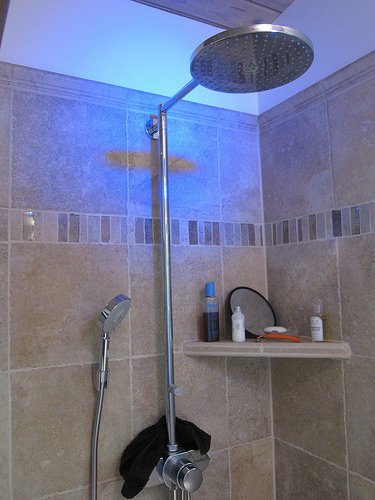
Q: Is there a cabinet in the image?
A: No, there are no cabinets.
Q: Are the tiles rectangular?
A: Yes, the tiles are rectangular.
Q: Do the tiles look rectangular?
A: Yes, the tiles are rectangular.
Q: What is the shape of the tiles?
A: The tiles are rectangular.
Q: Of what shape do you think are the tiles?
A: The tiles are rectangular.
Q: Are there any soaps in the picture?
A: Yes, there is a soap.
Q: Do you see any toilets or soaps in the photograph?
A: Yes, there is a soap.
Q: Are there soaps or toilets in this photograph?
A: Yes, there is a soap.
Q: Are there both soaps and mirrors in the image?
A: Yes, there are both a soap and a mirror.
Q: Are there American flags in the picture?
A: No, there are no American flags.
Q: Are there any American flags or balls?
A: No, there are no American flags or balls.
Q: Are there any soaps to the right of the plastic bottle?
A: Yes, there is a soap to the right of the bottle.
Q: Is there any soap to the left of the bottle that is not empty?
A: No, the soap is to the right of the bottle.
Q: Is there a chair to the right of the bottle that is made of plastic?
A: No, there is a soap to the right of the bottle.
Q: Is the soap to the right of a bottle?
A: Yes, the soap is to the right of a bottle.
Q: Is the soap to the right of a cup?
A: No, the soap is to the right of a bottle.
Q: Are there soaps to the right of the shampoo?
A: Yes, there is a soap to the right of the shampoo.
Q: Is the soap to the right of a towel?
A: No, the soap is to the right of a shampoo.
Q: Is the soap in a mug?
A: No, the soap is in a bottle.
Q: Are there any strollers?
A: No, there are no strollers.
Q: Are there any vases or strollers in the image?
A: No, there are no strollers or vases.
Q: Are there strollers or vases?
A: No, there are no strollers or vases.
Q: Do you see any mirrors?
A: Yes, there is a mirror.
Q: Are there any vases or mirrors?
A: Yes, there is a mirror.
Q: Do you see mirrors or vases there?
A: Yes, there is a mirror.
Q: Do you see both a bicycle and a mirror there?
A: No, there is a mirror but no bicycles.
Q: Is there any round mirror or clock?
A: Yes, there is a round mirror.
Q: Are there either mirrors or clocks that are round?
A: Yes, the mirror is round.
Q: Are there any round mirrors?
A: Yes, there is a round mirror.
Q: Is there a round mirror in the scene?
A: Yes, there is a round mirror.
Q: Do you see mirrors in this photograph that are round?
A: Yes, there is a round mirror.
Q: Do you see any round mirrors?
A: Yes, there is a round mirror.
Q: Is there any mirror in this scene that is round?
A: Yes, there is a mirror that is round.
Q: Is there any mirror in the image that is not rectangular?
A: Yes, there is a round mirror.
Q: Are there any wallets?
A: No, there are no wallets.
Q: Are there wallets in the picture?
A: No, there are no wallets.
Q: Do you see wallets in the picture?
A: No, there are no wallets.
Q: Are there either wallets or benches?
A: No, there are no wallets or benches.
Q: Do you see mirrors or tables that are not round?
A: No, there is a mirror but it is round.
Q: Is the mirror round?
A: Yes, the mirror is round.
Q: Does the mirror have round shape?
A: Yes, the mirror is round.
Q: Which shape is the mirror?
A: The mirror is round.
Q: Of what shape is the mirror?
A: The mirror is round.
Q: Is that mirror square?
A: No, the mirror is round.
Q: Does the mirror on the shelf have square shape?
A: No, the mirror is round.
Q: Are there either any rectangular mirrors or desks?
A: No, there is a mirror but it is round.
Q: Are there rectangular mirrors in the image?
A: No, there is a mirror but it is round.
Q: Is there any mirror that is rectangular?
A: No, there is a mirror but it is round.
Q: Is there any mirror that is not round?
A: No, there is a mirror but it is round.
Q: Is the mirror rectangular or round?
A: The mirror is round.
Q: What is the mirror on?
A: The mirror is on the shelf.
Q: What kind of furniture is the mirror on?
A: The mirror is on the shelf.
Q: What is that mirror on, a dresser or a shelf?
A: The mirror is on a shelf.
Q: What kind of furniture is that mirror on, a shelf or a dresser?
A: The mirror is on a shelf.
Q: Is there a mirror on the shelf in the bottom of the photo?
A: Yes, there is a mirror on the shelf.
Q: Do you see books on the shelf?
A: No, there is a mirror on the shelf.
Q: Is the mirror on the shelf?
A: Yes, the mirror is on the shelf.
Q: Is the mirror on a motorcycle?
A: No, the mirror is on the shelf.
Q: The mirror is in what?
A: The mirror is in the shower.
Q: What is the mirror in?
A: The mirror is in the shower.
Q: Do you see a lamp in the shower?
A: No, there is a mirror in the shower.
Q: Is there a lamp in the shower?
A: No, there is a mirror in the shower.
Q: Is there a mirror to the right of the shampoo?
A: Yes, there is a mirror to the right of the shampoo.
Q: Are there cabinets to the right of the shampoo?
A: No, there is a mirror to the right of the shampoo.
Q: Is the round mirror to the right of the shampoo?
A: Yes, the mirror is to the right of the shampoo.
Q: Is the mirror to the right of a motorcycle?
A: No, the mirror is to the right of the shampoo.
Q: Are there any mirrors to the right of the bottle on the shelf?
A: Yes, there is a mirror to the right of the bottle.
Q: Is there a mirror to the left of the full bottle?
A: No, the mirror is to the right of the bottle.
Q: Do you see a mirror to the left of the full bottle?
A: No, the mirror is to the right of the bottle.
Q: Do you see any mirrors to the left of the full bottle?
A: No, the mirror is to the right of the bottle.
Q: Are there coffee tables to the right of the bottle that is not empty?
A: No, there is a mirror to the right of the bottle.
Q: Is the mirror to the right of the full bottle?
A: Yes, the mirror is to the right of the bottle.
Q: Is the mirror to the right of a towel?
A: No, the mirror is to the right of the bottle.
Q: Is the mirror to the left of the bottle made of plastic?
A: No, the mirror is to the right of the bottle.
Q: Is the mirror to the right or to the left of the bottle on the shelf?
A: The mirror is to the right of the bottle.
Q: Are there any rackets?
A: No, there are no rackets.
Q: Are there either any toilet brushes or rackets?
A: No, there are no rackets or toilet brushes.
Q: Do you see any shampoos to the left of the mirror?
A: Yes, there is a shampoo to the left of the mirror.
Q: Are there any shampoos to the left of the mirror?
A: Yes, there is a shampoo to the left of the mirror.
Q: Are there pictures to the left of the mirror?
A: No, there is a shampoo to the left of the mirror.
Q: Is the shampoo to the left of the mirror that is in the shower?
A: Yes, the shampoo is to the left of the mirror.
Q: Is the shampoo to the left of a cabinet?
A: No, the shampoo is to the left of the mirror.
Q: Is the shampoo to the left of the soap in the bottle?
A: Yes, the shampoo is to the left of the soap.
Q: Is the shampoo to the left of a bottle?
A: Yes, the shampoo is to the left of a bottle.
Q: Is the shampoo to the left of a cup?
A: No, the shampoo is to the left of a bottle.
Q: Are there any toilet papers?
A: No, there are no toilet papers.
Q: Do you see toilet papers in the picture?
A: No, there are no toilet papers.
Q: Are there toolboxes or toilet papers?
A: No, there are no toilet papers or toolboxes.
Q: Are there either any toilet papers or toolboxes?
A: No, there are no toilet papers or toolboxes.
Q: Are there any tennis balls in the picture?
A: No, there are no tennis balls.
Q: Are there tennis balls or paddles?
A: No, there are no tennis balls or paddles.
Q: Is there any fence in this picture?
A: No, there are no fences.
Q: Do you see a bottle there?
A: Yes, there is a bottle.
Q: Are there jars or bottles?
A: Yes, there is a bottle.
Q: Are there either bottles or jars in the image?
A: Yes, there is a bottle.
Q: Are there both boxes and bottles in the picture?
A: No, there is a bottle but no boxes.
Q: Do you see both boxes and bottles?
A: No, there is a bottle but no boxes.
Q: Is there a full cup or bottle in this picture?
A: Yes, there is a full bottle.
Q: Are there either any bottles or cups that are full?
A: Yes, the bottle is full.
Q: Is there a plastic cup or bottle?
A: Yes, there is a plastic bottle.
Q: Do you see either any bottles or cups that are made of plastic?
A: Yes, the bottle is made of plastic.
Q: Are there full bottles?
A: Yes, there is a full bottle.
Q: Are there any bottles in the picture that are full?
A: Yes, there is a bottle that is full.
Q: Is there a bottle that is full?
A: Yes, there is a bottle that is full.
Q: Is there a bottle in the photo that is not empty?
A: Yes, there is an full bottle.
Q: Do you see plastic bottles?
A: Yes, there is a bottle that is made of plastic.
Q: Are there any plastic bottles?
A: Yes, there is a bottle that is made of plastic.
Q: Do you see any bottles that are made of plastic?
A: Yes, there is a bottle that is made of plastic.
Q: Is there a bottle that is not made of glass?
A: Yes, there is a bottle that is made of plastic.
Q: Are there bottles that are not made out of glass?
A: Yes, there is a bottle that is made of plastic.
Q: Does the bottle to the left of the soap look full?
A: Yes, the bottle is full.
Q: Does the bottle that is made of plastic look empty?
A: No, the bottle is full.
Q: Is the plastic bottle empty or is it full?
A: The bottle is full.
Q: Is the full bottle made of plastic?
A: Yes, the bottle is made of plastic.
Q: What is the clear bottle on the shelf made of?
A: The bottle is made of plastic.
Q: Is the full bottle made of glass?
A: No, the bottle is made of plastic.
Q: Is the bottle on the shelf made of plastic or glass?
A: The bottle is made of plastic.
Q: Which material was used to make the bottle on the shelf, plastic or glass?
A: The bottle is made of plastic.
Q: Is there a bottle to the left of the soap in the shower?
A: Yes, there is a bottle to the left of the soap.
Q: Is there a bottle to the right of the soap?
A: No, the bottle is to the left of the soap.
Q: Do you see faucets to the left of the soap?
A: No, there is a bottle to the left of the soap.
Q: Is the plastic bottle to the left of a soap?
A: Yes, the bottle is to the left of a soap.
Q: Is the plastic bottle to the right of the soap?
A: No, the bottle is to the left of the soap.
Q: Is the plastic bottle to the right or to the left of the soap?
A: The bottle is to the left of the soap.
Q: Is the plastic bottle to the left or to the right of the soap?
A: The bottle is to the left of the soap.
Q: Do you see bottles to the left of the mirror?
A: Yes, there is a bottle to the left of the mirror.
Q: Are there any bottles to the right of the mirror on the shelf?
A: No, the bottle is to the left of the mirror.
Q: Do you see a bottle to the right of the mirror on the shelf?
A: No, the bottle is to the left of the mirror.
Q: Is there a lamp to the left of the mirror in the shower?
A: No, there is a bottle to the left of the mirror.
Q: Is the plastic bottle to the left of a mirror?
A: Yes, the bottle is to the left of a mirror.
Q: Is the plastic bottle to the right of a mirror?
A: No, the bottle is to the left of a mirror.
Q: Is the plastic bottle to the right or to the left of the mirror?
A: The bottle is to the left of the mirror.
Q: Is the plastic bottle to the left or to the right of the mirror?
A: The bottle is to the left of the mirror.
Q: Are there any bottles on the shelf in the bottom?
A: Yes, there is a bottle on the shelf.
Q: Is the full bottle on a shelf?
A: Yes, the bottle is on a shelf.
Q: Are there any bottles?
A: Yes, there is a bottle.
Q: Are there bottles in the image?
A: Yes, there is a bottle.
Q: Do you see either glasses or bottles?
A: Yes, there is a bottle.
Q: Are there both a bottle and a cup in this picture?
A: No, there is a bottle but no cups.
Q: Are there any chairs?
A: No, there are no chairs.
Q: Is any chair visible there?
A: No, there are no chairs.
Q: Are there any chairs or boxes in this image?
A: No, there are no chairs or boxes.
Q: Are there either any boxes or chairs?
A: No, there are no chairs or boxes.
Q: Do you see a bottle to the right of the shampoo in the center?
A: Yes, there is a bottle to the right of the shampoo.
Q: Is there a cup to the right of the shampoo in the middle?
A: No, there is a bottle to the right of the shampoo.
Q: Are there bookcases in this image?
A: No, there are no bookcases.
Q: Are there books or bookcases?
A: No, there are no bookcases or books.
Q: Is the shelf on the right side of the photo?
A: Yes, the shelf is on the right of the image.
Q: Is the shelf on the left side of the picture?
A: No, the shelf is on the right of the image.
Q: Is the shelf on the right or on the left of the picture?
A: The shelf is on the right of the image.